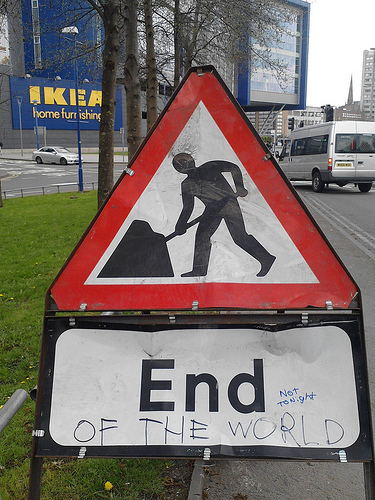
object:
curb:
[186, 458, 206, 500]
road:
[210, 193, 375, 500]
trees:
[0, 0, 310, 212]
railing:
[0, 183, 99, 206]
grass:
[0, 186, 193, 500]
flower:
[104, 480, 113, 491]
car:
[32, 146, 84, 166]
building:
[244, 98, 362, 150]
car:
[272, 120, 375, 193]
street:
[0, 155, 375, 500]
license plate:
[336, 162, 353, 166]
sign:
[6, 76, 123, 130]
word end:
[137, 359, 265, 412]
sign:
[47, 113, 358, 467]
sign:
[29, 63, 375, 500]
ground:
[0, 93, 375, 500]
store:
[1, 1, 306, 148]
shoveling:
[97, 190, 242, 277]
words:
[68, 411, 344, 447]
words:
[277, 387, 316, 408]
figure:
[171, 151, 276, 279]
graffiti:
[63, 412, 345, 447]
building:
[6, 33, 311, 111]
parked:
[7, 136, 98, 185]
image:
[83, 96, 317, 288]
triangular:
[45, 64, 362, 315]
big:
[8, 74, 125, 132]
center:
[41, 61, 358, 309]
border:
[39, 66, 362, 321]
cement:
[200, 462, 363, 500]